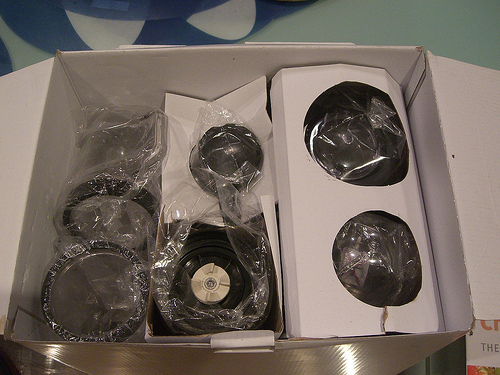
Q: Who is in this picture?
A: No one.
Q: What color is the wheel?
A: Black.